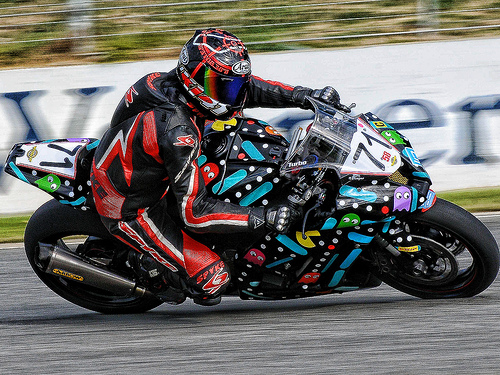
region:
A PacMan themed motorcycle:
[5, 111, 497, 312]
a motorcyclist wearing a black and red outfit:
[85, 22, 352, 310]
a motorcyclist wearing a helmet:
[171, 24, 256, 129]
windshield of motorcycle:
[283, 90, 408, 182]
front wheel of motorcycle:
[368, 185, 499, 303]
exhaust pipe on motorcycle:
[37, 242, 164, 310]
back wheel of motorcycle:
[22, 193, 166, 325]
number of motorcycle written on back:
[32, 130, 84, 180]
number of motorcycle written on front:
[345, 120, 397, 181]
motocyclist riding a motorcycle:
[9, 18, 497, 312]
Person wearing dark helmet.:
[185, 30, 265, 112]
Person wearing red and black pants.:
[149, 224, 201, 289]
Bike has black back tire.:
[26, 208, 122, 312]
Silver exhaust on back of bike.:
[43, 242, 125, 302]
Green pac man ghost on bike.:
[334, 214, 369, 237]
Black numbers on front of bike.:
[355, 121, 392, 163]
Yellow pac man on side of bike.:
[298, 224, 320, 252]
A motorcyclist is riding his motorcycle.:
[0, 0, 499, 374]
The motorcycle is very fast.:
[1, 0, 498, 374]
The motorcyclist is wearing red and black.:
[87, 26, 344, 316]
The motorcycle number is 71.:
[38, 138, 89, 176]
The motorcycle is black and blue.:
[6, 108, 497, 308]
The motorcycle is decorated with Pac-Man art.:
[2, 100, 432, 318]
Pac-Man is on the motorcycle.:
[295, 225, 325, 250]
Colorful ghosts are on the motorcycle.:
[302, 120, 412, 297]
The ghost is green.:
[31, 171, 61, 191]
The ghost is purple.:
[390, 185, 411, 211]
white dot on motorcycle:
[309, 265, 319, 275]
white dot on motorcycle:
[314, 260, 322, 270]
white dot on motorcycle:
[318, 254, 326, 264]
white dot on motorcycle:
[322, 248, 330, 258]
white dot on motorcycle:
[318, 238, 324, 245]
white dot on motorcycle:
[331, 234, 339, 245]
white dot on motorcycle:
[333, 223, 345, 235]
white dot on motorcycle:
[29, 168, 38, 177]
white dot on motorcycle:
[61, 178, 73, 188]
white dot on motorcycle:
[67, 188, 77, 200]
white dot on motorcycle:
[256, 125, 264, 137]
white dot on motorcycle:
[261, 141, 271, 150]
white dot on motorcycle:
[228, 130, 239, 138]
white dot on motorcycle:
[231, 142, 240, 150]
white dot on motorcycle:
[219, 157, 229, 167]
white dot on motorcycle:
[337, 199, 349, 206]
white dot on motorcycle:
[350, 200, 362, 213]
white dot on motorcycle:
[364, 202, 374, 212]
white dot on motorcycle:
[381, 194, 392, 203]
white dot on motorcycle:
[380, 179, 392, 190]